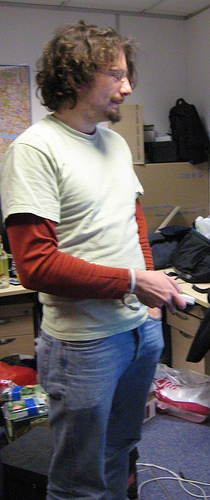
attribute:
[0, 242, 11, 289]
bottle — glass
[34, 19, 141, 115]
hair — shaggy, brown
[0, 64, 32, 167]
map — on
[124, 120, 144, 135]
box — folded, cardboard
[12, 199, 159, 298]
sleeves — orange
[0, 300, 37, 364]
drawers — light brown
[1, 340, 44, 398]
bag — red, white, plastic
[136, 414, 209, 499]
carpet — grey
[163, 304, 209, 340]
drawer — light brown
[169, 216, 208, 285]
bag — black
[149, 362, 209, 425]
plastic bag — red, white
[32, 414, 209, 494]
rug — blue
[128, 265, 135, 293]
wristband — white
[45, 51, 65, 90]
hair — curly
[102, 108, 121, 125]
goatee — brown